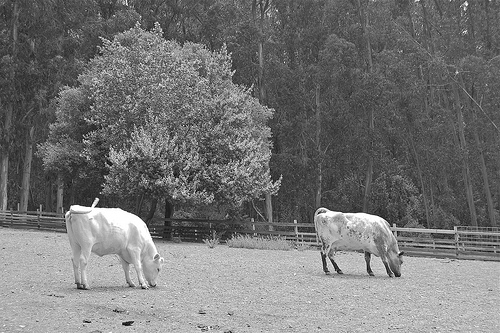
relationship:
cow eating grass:
[63, 196, 165, 289] [10, 228, 484, 316]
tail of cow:
[61, 195, 101, 215] [68, 182, 195, 304]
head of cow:
[134, 243, 170, 303] [63, 196, 165, 289]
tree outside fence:
[31, 19, 286, 242] [5, 203, 483, 268]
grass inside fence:
[227, 226, 301, 252] [408, 223, 498, 259]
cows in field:
[45, 176, 415, 301] [5, 219, 484, 328]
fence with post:
[404, 221, 484, 253] [454, 220, 475, 250]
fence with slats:
[404, 221, 484, 253] [411, 230, 448, 248]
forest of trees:
[3, 0, 499, 262] [7, 7, 484, 228]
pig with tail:
[53, 195, 166, 296] [61, 195, 101, 215]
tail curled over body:
[61, 195, 101, 215] [88, 202, 135, 262]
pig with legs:
[313, 203, 405, 280] [318, 247, 393, 276]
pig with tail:
[313, 203, 405, 280] [312, 205, 329, 239]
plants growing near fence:
[224, 230, 295, 252] [3, 200, 499, 261]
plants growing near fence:
[292, 233, 314, 250] [3, 200, 499, 261]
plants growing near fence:
[201, 237, 226, 248] [3, 200, 499, 261]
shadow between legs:
[73, 278, 147, 294] [312, 248, 392, 273]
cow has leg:
[63, 196, 165, 289] [130, 240, 153, 289]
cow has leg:
[63, 196, 165, 289] [118, 254, 138, 290]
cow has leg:
[63, 196, 165, 289] [77, 237, 95, 293]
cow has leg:
[63, 196, 165, 289] [73, 241, 82, 291]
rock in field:
[197, 308, 206, 317] [3, 226, 498, 331]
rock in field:
[111, 308, 126, 314] [3, 226, 498, 331]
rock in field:
[82, 319, 91, 327] [3, 226, 498, 331]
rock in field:
[122, 316, 133, 326] [3, 226, 498, 331]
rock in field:
[225, 308, 234, 316] [3, 226, 498, 331]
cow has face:
[56, 180, 185, 318] [145, 260, 166, 287]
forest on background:
[273, 37, 498, 231] [242, 86, 489, 142]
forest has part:
[357, 103, 465, 211] [433, 175, 451, 200]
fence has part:
[3, 200, 499, 261] [426, 234, 435, 248]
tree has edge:
[51, 19, 280, 268] [212, 175, 221, 182]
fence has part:
[397, 225, 457, 252] [430, 234, 446, 248]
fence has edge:
[350, 180, 498, 274] [432, 255, 446, 260]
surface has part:
[189, 276, 307, 316] [290, 295, 291, 302]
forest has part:
[3, 0, 499, 262] [350, 174, 353, 183]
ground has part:
[205, 258, 284, 316] [252, 281, 259, 295]